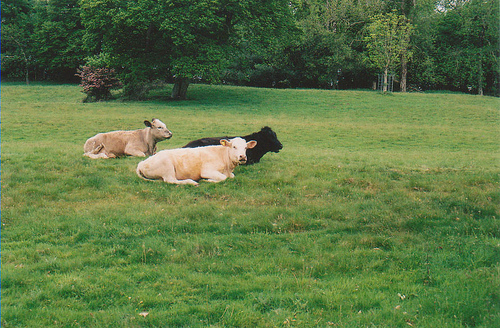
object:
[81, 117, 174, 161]
cow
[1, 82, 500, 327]
grass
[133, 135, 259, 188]
cow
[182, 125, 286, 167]
cow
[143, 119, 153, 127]
ear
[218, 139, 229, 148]
ear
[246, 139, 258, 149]
ear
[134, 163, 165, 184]
tail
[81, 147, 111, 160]
tail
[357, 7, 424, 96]
tree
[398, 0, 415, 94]
tree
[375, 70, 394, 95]
fence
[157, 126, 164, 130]
eye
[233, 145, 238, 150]
eye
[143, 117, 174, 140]
head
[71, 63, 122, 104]
bush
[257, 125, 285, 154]
head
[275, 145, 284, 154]
mouth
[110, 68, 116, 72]
flower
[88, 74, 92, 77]
flower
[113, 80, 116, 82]
flower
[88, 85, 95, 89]
flower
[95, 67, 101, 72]
flower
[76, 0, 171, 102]
tree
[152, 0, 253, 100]
tree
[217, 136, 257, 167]
head